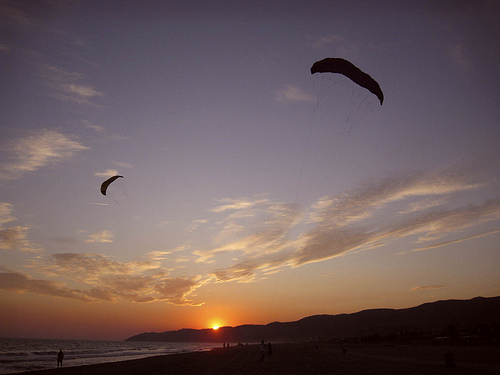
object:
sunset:
[186, 316, 235, 330]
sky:
[0, 0, 499, 341]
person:
[55, 346, 64, 368]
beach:
[0, 339, 498, 374]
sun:
[207, 317, 223, 338]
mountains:
[121, 294, 499, 341]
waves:
[0, 349, 47, 361]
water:
[0, 338, 237, 373]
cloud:
[50, 252, 124, 284]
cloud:
[154, 279, 199, 304]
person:
[267, 340, 274, 357]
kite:
[309, 57, 385, 107]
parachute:
[99, 173, 125, 196]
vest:
[260, 344, 264, 350]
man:
[258, 337, 264, 360]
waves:
[108, 345, 158, 353]